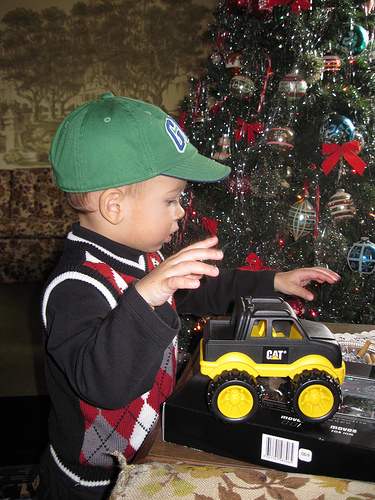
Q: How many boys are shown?
A: 1.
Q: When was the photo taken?
A: Christmas.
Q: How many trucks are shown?
A: 1.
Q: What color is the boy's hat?
A: Green.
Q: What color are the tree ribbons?
A: Red.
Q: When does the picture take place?
A: Christmas time.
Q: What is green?
A: Hat.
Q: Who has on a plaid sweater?
A: The boy.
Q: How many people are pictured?
A: One.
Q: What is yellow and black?
A: Truck.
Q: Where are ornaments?
A: On Christmas tree.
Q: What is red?
A: Ribbons.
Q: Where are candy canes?
A: On Christmas tree.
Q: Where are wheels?
A: On toy truck.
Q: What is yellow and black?
A: Toy truck.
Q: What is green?
A: Boy's hat.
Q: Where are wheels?
A: On truck.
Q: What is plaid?
A: Boy's sweater.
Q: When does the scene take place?
A: Christmas time.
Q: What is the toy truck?
A: A gift.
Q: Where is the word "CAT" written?
A: On side of truck.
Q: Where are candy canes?
A: In the tree.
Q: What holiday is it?
A: Christmas.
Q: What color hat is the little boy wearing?
A: Green.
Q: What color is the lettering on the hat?
A: Blue.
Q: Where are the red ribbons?
A: On christmas tree.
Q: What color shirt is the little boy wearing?
A: Black.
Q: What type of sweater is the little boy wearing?
A: Argyle vest.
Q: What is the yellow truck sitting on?
A: Black box.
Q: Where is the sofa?
A: In background.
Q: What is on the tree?
A: Ornaments.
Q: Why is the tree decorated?
A: Christmas holiday.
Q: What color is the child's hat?
A: Green.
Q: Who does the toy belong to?
A: The child.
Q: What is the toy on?
A: A table.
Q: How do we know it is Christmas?
A: Decorated tree.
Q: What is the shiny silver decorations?
A: Tinsel.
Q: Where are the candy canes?
A: On tree.